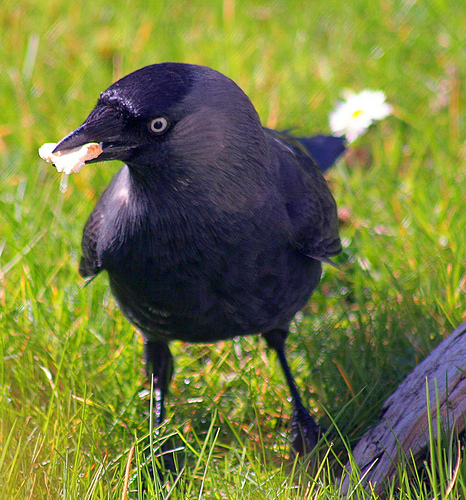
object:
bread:
[37, 139, 104, 174]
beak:
[52, 104, 134, 172]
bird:
[39, 61, 346, 475]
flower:
[326, 86, 391, 141]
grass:
[1, 2, 464, 498]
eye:
[151, 117, 167, 134]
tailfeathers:
[281, 123, 347, 178]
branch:
[338, 319, 465, 498]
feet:
[266, 329, 330, 456]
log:
[339, 320, 465, 498]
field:
[0, 0, 465, 500]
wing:
[266, 131, 343, 270]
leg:
[140, 335, 181, 486]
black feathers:
[80, 61, 346, 344]